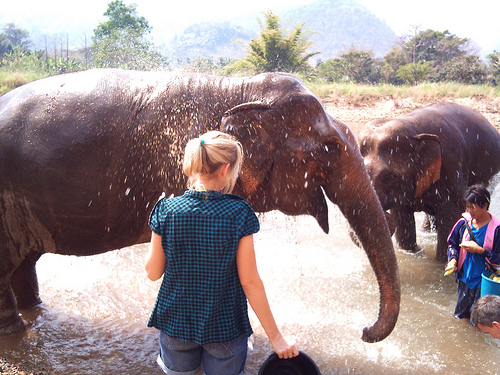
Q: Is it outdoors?
A: Yes, it is outdoors.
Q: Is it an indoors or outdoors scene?
A: It is outdoors.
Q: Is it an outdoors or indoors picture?
A: It is outdoors.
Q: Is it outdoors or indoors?
A: It is outdoors.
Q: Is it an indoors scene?
A: No, it is outdoors.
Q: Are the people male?
A: No, they are both male and female.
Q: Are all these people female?
A: No, they are both male and female.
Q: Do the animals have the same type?
A: Yes, all the animals are elephants.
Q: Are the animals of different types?
A: No, all the animals are elephants.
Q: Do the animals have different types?
A: No, all the animals are elephants.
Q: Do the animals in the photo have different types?
A: No, all the animals are elephants.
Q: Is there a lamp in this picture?
A: No, there are no lamps.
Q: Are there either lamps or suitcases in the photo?
A: No, there are no lamps or suitcases.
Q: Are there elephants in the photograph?
A: Yes, there is an elephant.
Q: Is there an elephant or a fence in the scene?
A: Yes, there is an elephant.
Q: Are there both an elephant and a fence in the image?
A: No, there is an elephant but no fences.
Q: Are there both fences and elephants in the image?
A: No, there is an elephant but no fences.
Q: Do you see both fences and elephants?
A: No, there is an elephant but no fences.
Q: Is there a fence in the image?
A: No, there are no fences.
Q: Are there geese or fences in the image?
A: No, there are no fences or geese.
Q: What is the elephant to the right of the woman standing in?
A: The elephant is standing in the water.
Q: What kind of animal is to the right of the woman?
A: The animal is an elephant.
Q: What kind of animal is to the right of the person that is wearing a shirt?
A: The animal is an elephant.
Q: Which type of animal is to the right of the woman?
A: The animal is an elephant.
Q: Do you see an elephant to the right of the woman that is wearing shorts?
A: Yes, there is an elephant to the right of the woman.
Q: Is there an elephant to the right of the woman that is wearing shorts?
A: Yes, there is an elephant to the right of the woman.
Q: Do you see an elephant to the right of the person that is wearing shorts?
A: Yes, there is an elephant to the right of the woman.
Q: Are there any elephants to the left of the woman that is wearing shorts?
A: No, the elephant is to the right of the woman.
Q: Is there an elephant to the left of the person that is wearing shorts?
A: No, the elephant is to the right of the woman.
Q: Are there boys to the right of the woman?
A: No, there is an elephant to the right of the woman.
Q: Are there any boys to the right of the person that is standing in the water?
A: No, there is an elephant to the right of the woman.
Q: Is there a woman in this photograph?
A: Yes, there is a woman.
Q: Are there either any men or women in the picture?
A: Yes, there is a woman.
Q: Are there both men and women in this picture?
A: Yes, there are both a woman and a man.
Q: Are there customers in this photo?
A: No, there are no customers.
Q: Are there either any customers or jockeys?
A: No, there are no customers or jockeys.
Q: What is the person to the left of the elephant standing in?
A: The woman is standing in the water.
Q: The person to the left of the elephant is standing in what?
A: The woman is standing in the water.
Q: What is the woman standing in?
A: The woman is standing in the water.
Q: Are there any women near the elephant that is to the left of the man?
A: Yes, there is a woman near the elephant.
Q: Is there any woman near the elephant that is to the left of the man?
A: Yes, there is a woman near the elephant.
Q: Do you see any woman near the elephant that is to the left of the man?
A: Yes, there is a woman near the elephant.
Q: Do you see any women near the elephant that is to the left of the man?
A: Yes, there is a woman near the elephant.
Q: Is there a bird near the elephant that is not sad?
A: No, there is a woman near the elephant.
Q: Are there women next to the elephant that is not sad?
A: Yes, there is a woman next to the elephant.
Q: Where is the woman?
A: The woman is in the water.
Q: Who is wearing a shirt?
A: The woman is wearing a shirt.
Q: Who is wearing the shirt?
A: The woman is wearing a shirt.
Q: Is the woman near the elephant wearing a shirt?
A: Yes, the woman is wearing a shirt.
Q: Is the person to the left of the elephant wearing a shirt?
A: Yes, the woman is wearing a shirt.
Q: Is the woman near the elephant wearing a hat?
A: No, the woman is wearing a shirt.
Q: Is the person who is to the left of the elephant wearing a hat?
A: No, the woman is wearing a shirt.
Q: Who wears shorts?
A: The woman wears shorts.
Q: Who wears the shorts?
A: The woman wears shorts.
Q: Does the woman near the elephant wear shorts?
A: Yes, the woman wears shorts.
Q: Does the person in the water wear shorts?
A: Yes, the woman wears shorts.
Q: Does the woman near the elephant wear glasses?
A: No, the woman wears shorts.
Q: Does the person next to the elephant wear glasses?
A: No, the woman wears shorts.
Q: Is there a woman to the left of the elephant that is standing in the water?
A: Yes, there is a woman to the left of the elephant.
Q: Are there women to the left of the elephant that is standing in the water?
A: Yes, there is a woman to the left of the elephant.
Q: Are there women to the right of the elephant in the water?
A: No, the woman is to the left of the elephant.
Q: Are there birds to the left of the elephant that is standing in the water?
A: No, there is a woman to the left of the elephant.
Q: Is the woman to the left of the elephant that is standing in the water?
A: Yes, the woman is to the left of the elephant.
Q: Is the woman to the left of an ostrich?
A: No, the woman is to the left of the elephant.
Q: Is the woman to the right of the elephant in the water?
A: No, the woman is to the left of the elephant.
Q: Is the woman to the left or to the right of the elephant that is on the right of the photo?
A: The woman is to the left of the elephant.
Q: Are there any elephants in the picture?
A: Yes, there is an elephant.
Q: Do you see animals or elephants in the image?
A: Yes, there is an elephant.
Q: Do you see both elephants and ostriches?
A: No, there is an elephant but no ostriches.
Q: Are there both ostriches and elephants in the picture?
A: No, there is an elephant but no ostriches.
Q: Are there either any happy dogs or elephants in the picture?
A: Yes, there is a happy elephant.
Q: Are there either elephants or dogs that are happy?
A: Yes, the elephant is happy.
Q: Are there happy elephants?
A: Yes, there is a happy elephant.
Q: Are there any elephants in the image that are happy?
A: Yes, there is an elephant that is happy.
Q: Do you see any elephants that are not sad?
A: Yes, there is a happy elephant.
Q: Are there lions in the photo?
A: No, there are no lions.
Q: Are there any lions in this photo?
A: No, there are no lions.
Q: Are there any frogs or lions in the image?
A: No, there are no lions or frogs.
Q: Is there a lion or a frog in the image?
A: No, there are no lions or frogs.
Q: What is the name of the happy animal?
A: The animal is an elephant.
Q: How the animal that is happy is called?
A: The animal is an elephant.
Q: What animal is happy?
A: The animal is an elephant.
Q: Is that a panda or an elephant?
A: That is an elephant.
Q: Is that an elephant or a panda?
A: That is an elephant.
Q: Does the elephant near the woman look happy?
A: Yes, the elephant is happy.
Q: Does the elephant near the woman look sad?
A: No, the elephant is happy.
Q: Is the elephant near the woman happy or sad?
A: The elephant is happy.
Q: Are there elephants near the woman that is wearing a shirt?
A: Yes, there is an elephant near the woman.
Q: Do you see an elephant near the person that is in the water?
A: Yes, there is an elephant near the woman.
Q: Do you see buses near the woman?
A: No, there is an elephant near the woman.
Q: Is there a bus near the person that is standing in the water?
A: No, there is an elephant near the woman.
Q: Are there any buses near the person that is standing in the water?
A: No, there is an elephant near the woman.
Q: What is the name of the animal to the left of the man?
A: The animal is an elephant.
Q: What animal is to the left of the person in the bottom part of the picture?
A: The animal is an elephant.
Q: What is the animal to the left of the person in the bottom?
A: The animal is an elephant.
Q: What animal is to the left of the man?
A: The animal is an elephant.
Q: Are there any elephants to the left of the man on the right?
A: Yes, there is an elephant to the left of the man.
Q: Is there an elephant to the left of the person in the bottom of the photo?
A: Yes, there is an elephant to the left of the man.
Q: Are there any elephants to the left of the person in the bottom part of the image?
A: Yes, there is an elephant to the left of the man.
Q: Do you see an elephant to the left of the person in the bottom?
A: Yes, there is an elephant to the left of the man.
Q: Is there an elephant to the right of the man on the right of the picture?
A: No, the elephant is to the left of the man.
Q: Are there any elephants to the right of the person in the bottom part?
A: No, the elephant is to the left of the man.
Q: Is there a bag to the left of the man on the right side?
A: No, there is an elephant to the left of the man.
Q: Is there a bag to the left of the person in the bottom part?
A: No, there is an elephant to the left of the man.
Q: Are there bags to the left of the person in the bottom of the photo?
A: No, there is an elephant to the left of the man.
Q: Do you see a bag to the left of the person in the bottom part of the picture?
A: No, there is an elephant to the left of the man.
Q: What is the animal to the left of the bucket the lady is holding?
A: The animal is an elephant.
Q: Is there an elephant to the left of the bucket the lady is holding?
A: Yes, there is an elephant to the left of the bucket.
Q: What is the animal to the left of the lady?
A: The animal is an elephant.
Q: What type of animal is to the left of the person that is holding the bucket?
A: The animal is an elephant.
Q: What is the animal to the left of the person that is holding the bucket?
A: The animal is an elephant.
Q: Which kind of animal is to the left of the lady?
A: The animal is an elephant.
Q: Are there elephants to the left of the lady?
A: Yes, there is an elephant to the left of the lady.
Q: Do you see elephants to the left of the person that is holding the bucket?
A: Yes, there is an elephant to the left of the lady.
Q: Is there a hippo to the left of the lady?
A: No, there is an elephant to the left of the lady.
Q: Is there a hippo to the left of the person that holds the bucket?
A: No, there is an elephant to the left of the lady.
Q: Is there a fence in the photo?
A: No, there are no fences.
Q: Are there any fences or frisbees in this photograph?
A: No, there are no fences or frisbees.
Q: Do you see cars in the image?
A: No, there are no cars.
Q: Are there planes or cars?
A: No, there are no cars or planes.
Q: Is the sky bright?
A: Yes, the sky is bright.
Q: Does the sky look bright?
A: Yes, the sky is bright.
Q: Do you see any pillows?
A: No, there are no pillows.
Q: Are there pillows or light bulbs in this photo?
A: No, there are no pillows or light bulbs.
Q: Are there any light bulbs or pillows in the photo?
A: No, there are no pillows or light bulbs.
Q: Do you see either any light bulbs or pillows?
A: No, there are no pillows or light bulbs.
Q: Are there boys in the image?
A: No, there are no boys.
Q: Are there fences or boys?
A: No, there are no boys or fences.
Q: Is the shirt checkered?
A: Yes, the shirt is checkered.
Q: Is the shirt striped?
A: No, the shirt is checkered.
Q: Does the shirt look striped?
A: No, the shirt is checkered.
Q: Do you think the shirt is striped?
A: No, the shirt is checkered.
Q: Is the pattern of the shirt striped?
A: No, the shirt is checkered.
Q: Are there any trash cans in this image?
A: No, there are no trash cans.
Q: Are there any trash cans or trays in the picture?
A: No, there are no trash cans or trays.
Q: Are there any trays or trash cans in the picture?
A: No, there are no trash cans or trays.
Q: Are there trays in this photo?
A: No, there are no trays.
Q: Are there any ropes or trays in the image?
A: No, there are no trays or ropes.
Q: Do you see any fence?
A: No, there are no fences.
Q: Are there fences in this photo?
A: No, there are no fences.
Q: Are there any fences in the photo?
A: No, there are no fences.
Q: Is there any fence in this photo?
A: No, there are no fences.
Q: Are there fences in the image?
A: No, there are no fences.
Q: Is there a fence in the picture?
A: No, there are no fences.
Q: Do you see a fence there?
A: No, there are no fences.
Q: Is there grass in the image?
A: Yes, there is grass.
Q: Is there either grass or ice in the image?
A: Yes, there is grass.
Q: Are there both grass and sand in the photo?
A: No, there is grass but no sand.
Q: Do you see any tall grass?
A: Yes, there is tall grass.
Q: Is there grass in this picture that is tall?
A: Yes, there is grass that is tall.